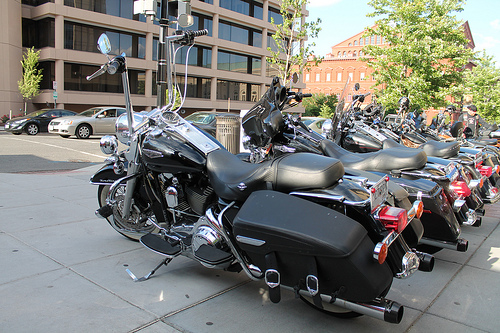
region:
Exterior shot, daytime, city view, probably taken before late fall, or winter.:
[1, 2, 493, 328]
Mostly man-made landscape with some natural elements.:
[0, 5, 495, 325]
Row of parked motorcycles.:
[92, 46, 497, 323]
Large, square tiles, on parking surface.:
[15, 177, 496, 328]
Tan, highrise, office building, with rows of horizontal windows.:
[10, 2, 305, 114]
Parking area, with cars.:
[10, 107, 161, 152]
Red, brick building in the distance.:
[318, 0, 496, 116]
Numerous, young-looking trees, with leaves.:
[15, 0, 497, 136]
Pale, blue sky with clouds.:
[326, 1, 367, 32]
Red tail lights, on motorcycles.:
[375, 147, 497, 272]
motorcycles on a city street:
[25, 5, 490, 317]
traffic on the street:
[8, 81, 249, 150]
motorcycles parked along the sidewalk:
[92, 21, 497, 271]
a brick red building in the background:
[301, 31, 477, 113]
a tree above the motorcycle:
[360, 6, 468, 98]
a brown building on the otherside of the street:
[40, 1, 311, 108]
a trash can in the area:
[210, 107, 243, 149]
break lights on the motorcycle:
[376, 160, 496, 249]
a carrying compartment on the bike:
[228, 193, 378, 308]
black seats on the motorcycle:
[220, 132, 466, 197]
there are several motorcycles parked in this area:
[62, 54, 498, 305]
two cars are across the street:
[7, 78, 110, 147]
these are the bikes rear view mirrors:
[86, 15, 214, 52]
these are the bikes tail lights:
[367, 193, 427, 258]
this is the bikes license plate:
[348, 172, 408, 208]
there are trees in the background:
[270, 12, 479, 100]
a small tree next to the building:
[16, 30, 35, 115]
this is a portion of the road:
[5, 127, 99, 162]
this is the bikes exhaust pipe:
[308, 288, 412, 323]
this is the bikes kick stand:
[105, 248, 185, 293]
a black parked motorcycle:
[84, 13, 434, 321]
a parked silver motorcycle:
[238, 75, 470, 268]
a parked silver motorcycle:
[315, 88, 486, 235]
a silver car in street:
[44, 103, 121, 140]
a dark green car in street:
[4, 105, 76, 135]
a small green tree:
[18, 44, 41, 116]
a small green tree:
[273, 0, 326, 100]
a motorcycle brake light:
[374, 203, 409, 230]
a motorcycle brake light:
[448, 178, 470, 198]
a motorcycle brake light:
[476, 161, 492, 176]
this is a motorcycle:
[69, 99, 404, 329]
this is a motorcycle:
[194, 93, 436, 278]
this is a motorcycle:
[448, 122, 498, 169]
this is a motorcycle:
[326, 81, 496, 226]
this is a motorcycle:
[373, 91, 493, 188]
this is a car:
[43, 98, 146, 143]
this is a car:
[0, 98, 86, 143]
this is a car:
[174, 97, 266, 150]